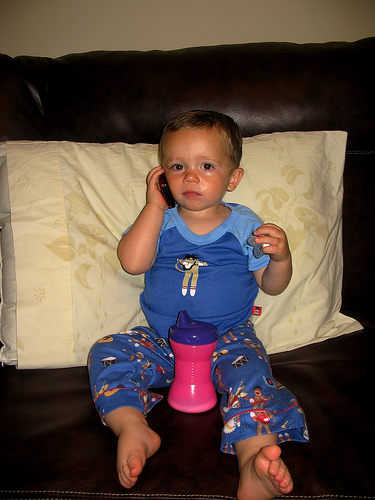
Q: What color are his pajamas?
A: Blue.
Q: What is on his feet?
A: He is barefoot.